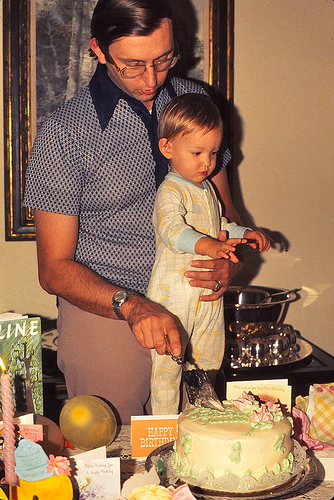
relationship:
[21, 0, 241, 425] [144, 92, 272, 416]
man standing with baby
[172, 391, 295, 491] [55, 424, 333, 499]
cake on top of table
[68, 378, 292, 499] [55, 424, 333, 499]
birthday cards on top of table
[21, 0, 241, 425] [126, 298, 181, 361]
man has right hand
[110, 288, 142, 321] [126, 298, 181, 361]
watch worn above right hand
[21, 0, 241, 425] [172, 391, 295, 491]
man cutting into cake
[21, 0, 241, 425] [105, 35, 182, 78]
man wearing glasses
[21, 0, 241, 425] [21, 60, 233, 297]
man wearing shirt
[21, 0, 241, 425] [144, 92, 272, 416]
man holding baby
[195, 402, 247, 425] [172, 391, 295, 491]
icing on top of cake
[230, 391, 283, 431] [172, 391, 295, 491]
roses on top of cake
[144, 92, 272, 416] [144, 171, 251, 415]
baby wearing pajamas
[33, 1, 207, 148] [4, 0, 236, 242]
tree picture inside of frame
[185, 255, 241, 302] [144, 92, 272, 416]
hand in front of baby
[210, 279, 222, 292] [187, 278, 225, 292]
ring worn on finger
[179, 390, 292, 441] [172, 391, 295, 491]
top of a cake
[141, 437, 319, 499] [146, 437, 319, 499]
edge of cake plate